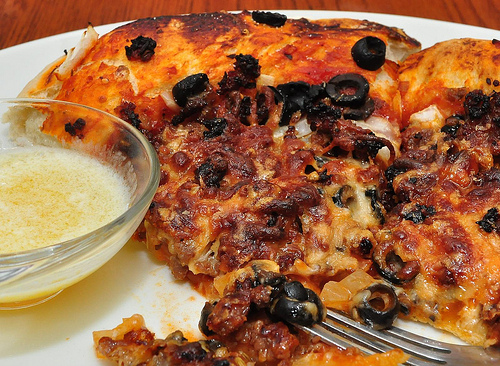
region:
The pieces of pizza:
[0, 6, 497, 362]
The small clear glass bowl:
[0, 90, 161, 305]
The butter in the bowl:
[0, 140, 125, 251]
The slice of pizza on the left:
[16, 5, 416, 360]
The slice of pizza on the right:
[385, 30, 495, 360]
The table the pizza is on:
[0, 0, 497, 51]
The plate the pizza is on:
[1, 8, 498, 364]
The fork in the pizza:
[276, 288, 498, 363]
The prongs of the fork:
[295, 301, 454, 365]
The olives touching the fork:
[258, 271, 398, 343]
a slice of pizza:
[68, 9, 409, 314]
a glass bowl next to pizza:
[1, 95, 151, 311]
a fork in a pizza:
[298, 280, 498, 362]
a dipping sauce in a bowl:
[2, 117, 132, 260]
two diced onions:
[322, 265, 376, 306]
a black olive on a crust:
[354, 30, 389, 65]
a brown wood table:
[1, 1, 499, 51]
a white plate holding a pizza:
[0, 10, 498, 364]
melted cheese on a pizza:
[418, 219, 497, 305]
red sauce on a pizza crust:
[302, 55, 327, 79]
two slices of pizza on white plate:
[26, 16, 426, 363]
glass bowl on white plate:
[12, 74, 174, 301]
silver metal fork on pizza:
[272, 231, 467, 359]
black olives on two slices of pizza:
[158, 51, 420, 262]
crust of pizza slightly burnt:
[82, 0, 356, 96]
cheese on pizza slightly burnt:
[145, 46, 497, 356]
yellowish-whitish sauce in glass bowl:
[13, 111, 131, 279]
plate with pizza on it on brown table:
[0, 11, 460, 363]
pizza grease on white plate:
[123, 261, 225, 357]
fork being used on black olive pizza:
[254, 277, 497, 355]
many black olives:
[158, 55, 415, 119]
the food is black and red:
[66, 37, 498, 346]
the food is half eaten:
[89, 30, 496, 357]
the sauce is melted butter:
[25, 104, 134, 304]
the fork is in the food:
[265, 254, 461, 364]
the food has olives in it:
[61, 22, 498, 357]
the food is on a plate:
[25, 21, 492, 363]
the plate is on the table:
[13, 10, 496, 361]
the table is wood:
[11, 5, 121, 27]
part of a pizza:
[217, 46, 264, 113]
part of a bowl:
[66, 237, 108, 287]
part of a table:
[28, 320, 60, 348]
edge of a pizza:
[200, 272, 247, 357]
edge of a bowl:
[83, 222, 108, 239]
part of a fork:
[406, 313, 437, 351]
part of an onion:
[364, 280, 404, 328]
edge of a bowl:
[61, 210, 120, 255]